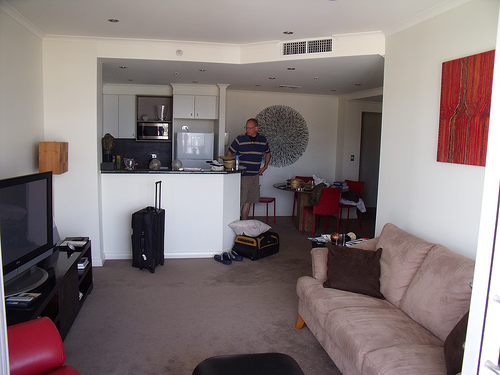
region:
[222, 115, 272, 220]
man standing in home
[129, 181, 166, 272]
upright black rolling suitcase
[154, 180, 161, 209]
suitcase handle is extended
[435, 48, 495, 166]
red and brown abstract artwork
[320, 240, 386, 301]
brown throw pillow on couch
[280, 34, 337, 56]
AC vent opening on ceiling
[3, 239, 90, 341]
shiny black entertainment center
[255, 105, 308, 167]
large round decoration on wall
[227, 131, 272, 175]
man wearing blue shirt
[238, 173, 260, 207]
man wearing khaki shorts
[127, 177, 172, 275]
the black suitcase has a long handle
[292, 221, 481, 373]
the couch is light brown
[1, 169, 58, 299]
the television is black and silver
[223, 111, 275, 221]
a man is standing near the kitchen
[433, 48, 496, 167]
a red painting on the wall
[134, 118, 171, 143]
the microwave is silver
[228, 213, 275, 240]
the pillow is white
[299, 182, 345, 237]
the chair at the table is red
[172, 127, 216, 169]
the refrigerator is white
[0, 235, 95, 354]
the entertainment stand is black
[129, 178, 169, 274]
black suitcase on floor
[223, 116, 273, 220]
man wearing glasses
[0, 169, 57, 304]
Television on the table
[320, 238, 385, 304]
brown pillow on couch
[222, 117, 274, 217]
man wearing stripe shirt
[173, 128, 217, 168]
white fridge in kitchen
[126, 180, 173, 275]
luggage with pull handle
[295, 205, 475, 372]
beige couch in front of television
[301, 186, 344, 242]
red plastic chair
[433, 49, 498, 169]
bright painting on the wall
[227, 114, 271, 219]
A man in a striped shirt standing up.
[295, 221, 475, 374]
A light brown suede couch.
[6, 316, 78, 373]
The arm of a red leather chair.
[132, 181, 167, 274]
A tall black suitcase with extended handle.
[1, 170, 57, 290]
A black and grey television.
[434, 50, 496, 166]
A mostly red painting on the wall.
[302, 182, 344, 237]
A red chair sitting at the table to the right of a man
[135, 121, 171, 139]
Small silver and black microwave.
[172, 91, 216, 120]
Two small white cabinets over a fridge.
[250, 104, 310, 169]
A large round black decoration behind a man.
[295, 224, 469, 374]
a light tan couch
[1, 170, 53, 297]
a flat screen TV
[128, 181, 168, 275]
a black rolling luggage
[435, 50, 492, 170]
a red piece of artwork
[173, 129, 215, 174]
a white refrigerator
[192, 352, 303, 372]
a black ottoman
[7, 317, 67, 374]
a red chair arm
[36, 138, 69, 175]
a square lamp shade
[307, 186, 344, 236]
a red kitchen chair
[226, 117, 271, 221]
a man standing in kitchen